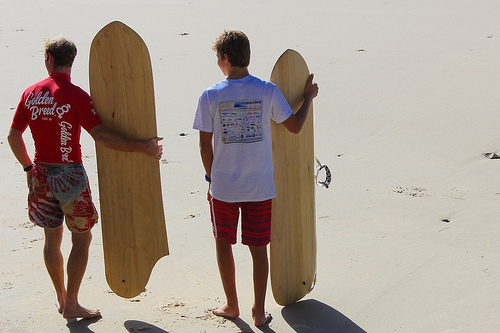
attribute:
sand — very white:
[2, 2, 497, 330]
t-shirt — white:
[192, 74, 292, 202]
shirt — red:
[9, 75, 104, 164]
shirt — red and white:
[18, 67, 138, 197]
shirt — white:
[192, 79, 291, 204]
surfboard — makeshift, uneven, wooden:
[84, 23, 180, 310]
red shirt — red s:
[11, 76, 96, 163]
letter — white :
[54, 115, 74, 135]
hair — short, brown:
[234, 39, 243, 46]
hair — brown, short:
[46, 43, 63, 50]